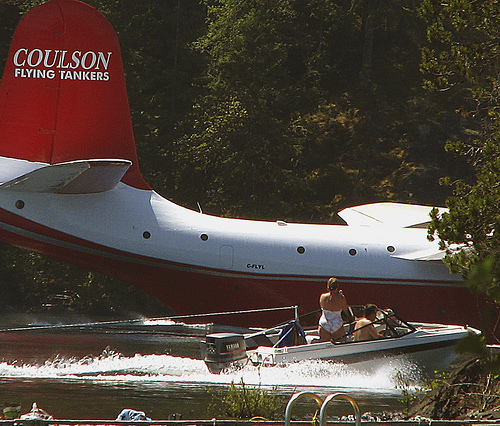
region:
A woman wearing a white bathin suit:
[309, 265, 358, 351]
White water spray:
[275, 363, 421, 390]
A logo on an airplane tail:
[3, 27, 128, 91]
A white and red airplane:
[5, 6, 496, 338]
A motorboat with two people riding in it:
[183, 274, 498, 394]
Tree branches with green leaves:
[410, 168, 499, 293]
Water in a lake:
[13, 331, 202, 411]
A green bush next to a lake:
[191, 371, 303, 418]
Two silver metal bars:
[277, 385, 368, 424]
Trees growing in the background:
[166, 11, 431, 199]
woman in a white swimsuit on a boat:
[319, 278, 346, 343]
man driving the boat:
[353, 303, 384, 339]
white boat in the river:
[201, 303, 481, 385]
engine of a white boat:
[205, 331, 248, 376]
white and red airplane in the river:
[1, 0, 498, 352]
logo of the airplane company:
[13, 48, 111, 78]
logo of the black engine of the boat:
[225, 343, 239, 350]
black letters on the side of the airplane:
[248, 263, 265, 268]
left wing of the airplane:
[337, 199, 452, 228]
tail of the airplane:
[0, 1, 182, 321]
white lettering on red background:
[9, 44, 113, 85]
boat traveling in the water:
[195, 288, 485, 374]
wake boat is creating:
[8, 346, 410, 386]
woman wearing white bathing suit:
[313, 277, 347, 338]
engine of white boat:
[203, 329, 246, 372]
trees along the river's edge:
[5, 2, 490, 279]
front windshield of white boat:
[342, 300, 407, 338]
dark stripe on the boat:
[330, 327, 476, 367]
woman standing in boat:
[311, 270, 354, 340]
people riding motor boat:
[201, 270, 486, 373]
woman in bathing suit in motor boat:
[314, 271, 363, 358]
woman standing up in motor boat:
[302, 265, 362, 364]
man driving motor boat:
[349, 291, 428, 355]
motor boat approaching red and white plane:
[8, 127, 463, 415]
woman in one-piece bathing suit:
[314, 271, 353, 339]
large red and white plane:
[5, 104, 454, 334]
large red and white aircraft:
[3, 100, 466, 340]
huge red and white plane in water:
[2, 103, 458, 356]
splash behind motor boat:
[43, 343, 425, 425]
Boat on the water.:
[172, 260, 489, 396]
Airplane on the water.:
[0, 5, 491, 355]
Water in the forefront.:
[0, 321, 495, 418]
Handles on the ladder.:
[277, 383, 364, 424]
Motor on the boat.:
[200, 325, 259, 381]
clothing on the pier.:
[112, 405, 147, 422]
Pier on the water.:
[2, 408, 497, 424]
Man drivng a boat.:
[350, 299, 378, 342]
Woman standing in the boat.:
[317, 275, 352, 344]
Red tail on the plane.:
[7, 3, 152, 190]